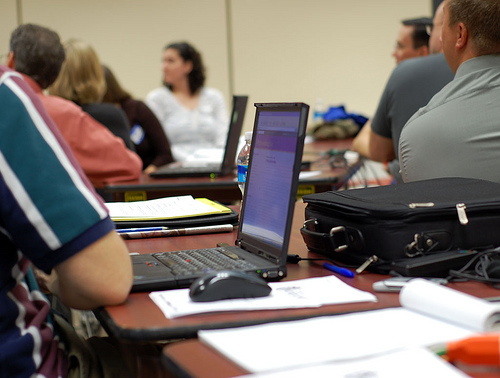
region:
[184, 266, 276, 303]
a black computer mouse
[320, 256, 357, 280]
a blue ink pen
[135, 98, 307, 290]
a laptop computer on a table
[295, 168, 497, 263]
a black bag on a table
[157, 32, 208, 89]
a woman with brown hair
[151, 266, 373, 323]
a piece of paper with a computer mouse on it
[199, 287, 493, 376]
a note pad on a table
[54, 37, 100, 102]
a woman with blonde hair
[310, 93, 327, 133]
a plastic water bottle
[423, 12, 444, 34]
a man wearing glasses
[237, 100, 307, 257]
The laptop is turned on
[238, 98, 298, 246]
Screen is lit on the laptop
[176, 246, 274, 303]
Mouse near a laptop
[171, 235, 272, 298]
Black colored mouse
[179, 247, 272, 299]
Black colored mouse near a laptop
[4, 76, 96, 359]
The person has a striped shirt on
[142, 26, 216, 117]
The woman has a white shirt on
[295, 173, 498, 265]
closed black travel case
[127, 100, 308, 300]
open black laptop and mouse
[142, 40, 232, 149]
woman wearing a white shirt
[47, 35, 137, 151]
woman with short blonde hair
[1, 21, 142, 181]
gray haired man in light red shirt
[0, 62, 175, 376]
man in striped shirt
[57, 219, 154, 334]
elbow resting on a table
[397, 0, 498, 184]
man in tight grey shirt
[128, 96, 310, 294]
A black laptop on a table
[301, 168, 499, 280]
A black briefcase on a table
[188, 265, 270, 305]
A grey and black computer mouse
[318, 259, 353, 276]
A blue marker on a table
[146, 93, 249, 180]
a black laptop on a table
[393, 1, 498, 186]
A person in a grey shirt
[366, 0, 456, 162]
A person in a grey shirt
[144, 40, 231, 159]
a woman in a white shirt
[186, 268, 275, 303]
Wireless computer mouse for laptop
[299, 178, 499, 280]
Black canvas computer case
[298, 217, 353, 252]
Black handle on computer case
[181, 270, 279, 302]
computer mouse on paper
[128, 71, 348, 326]
The laptop is black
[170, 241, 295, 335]
The mouse is black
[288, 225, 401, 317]
The blue pen is on the desk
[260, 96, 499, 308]
The black bag is on the desk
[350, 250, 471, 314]
The silver phone is on the desk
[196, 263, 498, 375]
The pad of paper is on the desk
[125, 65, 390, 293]
The laptop is on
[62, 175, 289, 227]
The paper is yellow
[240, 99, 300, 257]
laptop screen is on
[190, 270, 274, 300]
computer mouse is wireless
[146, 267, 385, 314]
computer mouse is on papers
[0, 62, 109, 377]
white stripes on the shirt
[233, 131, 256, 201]
water bottle next to laptop screen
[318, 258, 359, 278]
pen is blue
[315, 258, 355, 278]
pen is next to papers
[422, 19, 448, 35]
man is wearing glasses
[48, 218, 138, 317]
person's elbow is on the table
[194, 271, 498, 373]
pad of paper next to mouse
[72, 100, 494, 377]
a group of desks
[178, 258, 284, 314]
a black computer mouse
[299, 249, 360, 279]
blue pen on the desk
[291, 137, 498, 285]
a black laptop case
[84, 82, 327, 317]
laptop on a desk